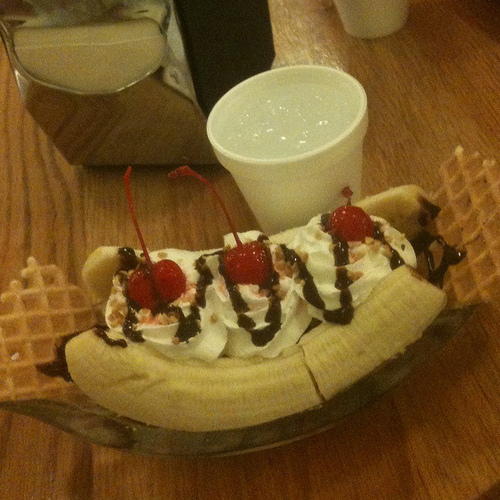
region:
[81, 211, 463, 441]
Banana ice cream sundae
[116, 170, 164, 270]
Red stem on a cherry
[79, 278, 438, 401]
Long banana slice in ice cream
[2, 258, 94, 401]
Waffle ice cream cone in a sundae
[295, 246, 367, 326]
Brown chocolate sauce on whipped cream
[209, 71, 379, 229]
White cup with liquid inside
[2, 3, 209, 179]
Silver napkin holder on a table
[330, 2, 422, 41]
Bottom of white cup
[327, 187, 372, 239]
Red cherry with small stem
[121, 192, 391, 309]
Three cherries on whipped cream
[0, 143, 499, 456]
A banana split with whip cream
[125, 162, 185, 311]
A red cherry on top of banana split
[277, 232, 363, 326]
chocolate syrup on top of banana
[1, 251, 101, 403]
waffle cone on banana split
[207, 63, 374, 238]
clear drink in foam cup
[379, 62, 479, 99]
a wooden table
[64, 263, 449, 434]
split banana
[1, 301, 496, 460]
A clear bowl with banana split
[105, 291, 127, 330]
peanuts on top of banana split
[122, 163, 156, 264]
a cherry stem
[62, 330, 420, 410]
Banana with a break in it.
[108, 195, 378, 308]
Three cherries with stems.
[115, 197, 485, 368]
Whipped cream with chocolate syrup, nuts and cherries.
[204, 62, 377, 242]
Styrofoam cup containing ice water.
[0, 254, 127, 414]
Ice cream cone type wafer.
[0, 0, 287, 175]
Chrome and black napkin dispenser.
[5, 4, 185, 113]
White paper napkins inside mouth of dispenser.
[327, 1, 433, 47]
Bottom of a white styrofoam cup.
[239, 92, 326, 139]
Crushed ice and water.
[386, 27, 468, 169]
Wooden surface.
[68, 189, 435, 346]
three cherries on a banana split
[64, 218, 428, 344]
nuts on a banana split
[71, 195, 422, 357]
whip cream on a banana split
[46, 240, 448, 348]
chocolate syrup on a banana split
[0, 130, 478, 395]
two waffle chips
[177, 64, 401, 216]
white cup of water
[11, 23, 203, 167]
silver napkin holder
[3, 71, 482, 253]
wooden restaurant table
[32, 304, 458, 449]
clear ice cream dish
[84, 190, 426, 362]
ice cream on a banana split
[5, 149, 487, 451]
banana split on waffle cone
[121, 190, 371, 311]
three cherries on top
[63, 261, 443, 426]
half a banana that is broken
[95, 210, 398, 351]
zig zag chocolate syrup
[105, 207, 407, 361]
mounds of whipped cream toppings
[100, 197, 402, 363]
three scoops of ice cream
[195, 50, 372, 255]
styrofoam cup of a drink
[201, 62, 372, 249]
cup of water with ice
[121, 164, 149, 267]
maraschino cherry stem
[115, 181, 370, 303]
three maraschino cherries on top